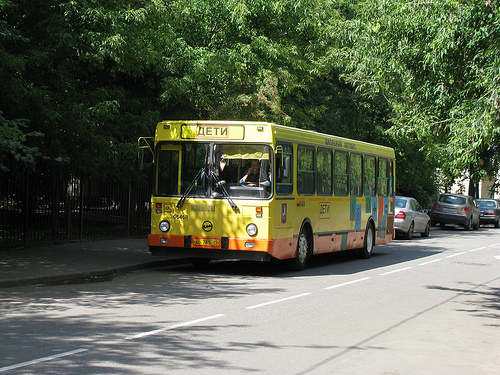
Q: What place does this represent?
A: It represents the street.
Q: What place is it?
A: It is a street.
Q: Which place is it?
A: It is a street.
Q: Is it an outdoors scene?
A: Yes, it is outdoors.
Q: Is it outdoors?
A: Yes, it is outdoors.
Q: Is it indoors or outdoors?
A: It is outdoors.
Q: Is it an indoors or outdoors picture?
A: It is outdoors.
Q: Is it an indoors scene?
A: No, it is outdoors.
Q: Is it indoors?
A: No, it is outdoors.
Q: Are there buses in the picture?
A: Yes, there is a bus.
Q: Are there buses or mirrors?
A: Yes, there is a bus.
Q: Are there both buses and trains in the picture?
A: No, there is a bus but no trains.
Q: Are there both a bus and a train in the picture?
A: No, there is a bus but no trains.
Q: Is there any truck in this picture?
A: No, there are no trucks.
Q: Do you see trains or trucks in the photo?
A: No, there are no trucks or trains.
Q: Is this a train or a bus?
A: This is a bus.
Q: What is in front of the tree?
A: The bus is in front of the tree.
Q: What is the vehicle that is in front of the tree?
A: The vehicle is a bus.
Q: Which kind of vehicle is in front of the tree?
A: The vehicle is a bus.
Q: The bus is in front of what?
A: The bus is in front of the tree.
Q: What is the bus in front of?
A: The bus is in front of the tree.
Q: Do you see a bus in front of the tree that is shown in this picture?
A: Yes, there is a bus in front of the tree.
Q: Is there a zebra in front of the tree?
A: No, there is a bus in front of the tree.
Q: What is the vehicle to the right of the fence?
A: The vehicle is a bus.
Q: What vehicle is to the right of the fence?
A: The vehicle is a bus.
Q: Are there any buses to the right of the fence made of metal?
A: Yes, there is a bus to the right of the fence.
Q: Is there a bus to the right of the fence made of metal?
A: Yes, there is a bus to the right of the fence.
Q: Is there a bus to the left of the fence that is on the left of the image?
A: No, the bus is to the right of the fence.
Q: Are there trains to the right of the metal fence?
A: No, there is a bus to the right of the fence.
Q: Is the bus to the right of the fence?
A: Yes, the bus is to the right of the fence.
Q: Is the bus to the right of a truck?
A: No, the bus is to the right of the fence.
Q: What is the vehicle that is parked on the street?
A: The vehicle is a bus.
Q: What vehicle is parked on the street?
A: The vehicle is a bus.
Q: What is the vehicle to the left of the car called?
A: The vehicle is a bus.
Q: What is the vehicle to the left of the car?
A: The vehicle is a bus.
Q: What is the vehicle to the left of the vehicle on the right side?
A: The vehicle is a bus.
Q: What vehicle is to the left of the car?
A: The vehicle is a bus.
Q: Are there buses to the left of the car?
A: Yes, there is a bus to the left of the car.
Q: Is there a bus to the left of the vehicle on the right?
A: Yes, there is a bus to the left of the car.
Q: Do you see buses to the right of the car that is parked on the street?
A: No, the bus is to the left of the car.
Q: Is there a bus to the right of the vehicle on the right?
A: No, the bus is to the left of the car.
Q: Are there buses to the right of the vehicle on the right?
A: No, the bus is to the left of the car.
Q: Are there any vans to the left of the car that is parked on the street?
A: No, there is a bus to the left of the car.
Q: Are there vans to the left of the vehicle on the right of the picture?
A: No, there is a bus to the left of the car.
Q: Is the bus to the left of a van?
A: No, the bus is to the left of the car.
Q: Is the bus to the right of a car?
A: No, the bus is to the left of a car.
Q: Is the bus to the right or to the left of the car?
A: The bus is to the left of the car.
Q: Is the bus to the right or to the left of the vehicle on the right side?
A: The bus is to the left of the car.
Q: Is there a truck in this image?
A: No, there are no trucks.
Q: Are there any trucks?
A: No, there are no trucks.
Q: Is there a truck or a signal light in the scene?
A: No, there are no trucks or traffic lights.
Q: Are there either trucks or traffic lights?
A: No, there are no trucks or traffic lights.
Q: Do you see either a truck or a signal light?
A: No, there are no trucks or traffic lights.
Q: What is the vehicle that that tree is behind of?
A: The vehicle is a bus.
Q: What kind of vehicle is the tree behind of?
A: The tree is behind the bus.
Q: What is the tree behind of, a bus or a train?
A: The tree is behind a bus.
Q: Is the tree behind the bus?
A: Yes, the tree is behind the bus.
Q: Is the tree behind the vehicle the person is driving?
A: Yes, the tree is behind the bus.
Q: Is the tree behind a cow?
A: No, the tree is behind the bus.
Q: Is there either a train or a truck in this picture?
A: No, there are no trucks or trains.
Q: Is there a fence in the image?
A: Yes, there is a fence.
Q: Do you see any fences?
A: Yes, there is a fence.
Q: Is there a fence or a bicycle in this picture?
A: Yes, there is a fence.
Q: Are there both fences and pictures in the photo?
A: No, there is a fence but no pictures.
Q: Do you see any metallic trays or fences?
A: Yes, there is a metal fence.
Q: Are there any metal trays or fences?
A: Yes, there is a metal fence.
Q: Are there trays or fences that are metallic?
A: Yes, the fence is metallic.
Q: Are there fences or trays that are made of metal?
A: Yes, the fence is made of metal.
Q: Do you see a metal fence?
A: Yes, there is a metal fence.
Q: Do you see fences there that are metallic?
A: Yes, there is a fence that is metallic.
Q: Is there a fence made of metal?
A: Yes, there is a fence that is made of metal.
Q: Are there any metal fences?
A: Yes, there is a fence that is made of metal.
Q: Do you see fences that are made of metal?
A: Yes, there is a fence that is made of metal.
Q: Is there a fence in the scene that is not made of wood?
A: Yes, there is a fence that is made of metal.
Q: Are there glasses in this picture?
A: No, there are no glasses.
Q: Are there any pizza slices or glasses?
A: No, there are no glasses or pizza slices.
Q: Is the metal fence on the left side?
A: Yes, the fence is on the left of the image.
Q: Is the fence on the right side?
A: No, the fence is on the left of the image.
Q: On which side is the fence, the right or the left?
A: The fence is on the left of the image.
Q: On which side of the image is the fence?
A: The fence is on the left of the image.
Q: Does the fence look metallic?
A: Yes, the fence is metallic.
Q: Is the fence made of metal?
A: Yes, the fence is made of metal.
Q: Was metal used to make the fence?
A: Yes, the fence is made of metal.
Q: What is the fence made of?
A: The fence is made of metal.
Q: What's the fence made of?
A: The fence is made of metal.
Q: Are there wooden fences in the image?
A: No, there is a fence but it is metallic.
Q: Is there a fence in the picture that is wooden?
A: No, there is a fence but it is metallic.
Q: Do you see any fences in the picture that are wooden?
A: No, there is a fence but it is metallic.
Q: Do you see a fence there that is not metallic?
A: No, there is a fence but it is metallic.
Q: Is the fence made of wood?
A: No, the fence is made of metal.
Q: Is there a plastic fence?
A: No, there is a fence but it is made of metal.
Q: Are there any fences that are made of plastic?
A: No, there is a fence but it is made of metal.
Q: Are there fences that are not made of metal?
A: No, there is a fence but it is made of metal.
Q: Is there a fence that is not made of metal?
A: No, there is a fence but it is made of metal.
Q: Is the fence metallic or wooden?
A: The fence is metallic.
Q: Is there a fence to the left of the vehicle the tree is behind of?
A: Yes, there is a fence to the left of the bus.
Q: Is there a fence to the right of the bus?
A: No, the fence is to the left of the bus.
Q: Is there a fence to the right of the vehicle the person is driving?
A: No, the fence is to the left of the bus.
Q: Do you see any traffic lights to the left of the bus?
A: No, there is a fence to the left of the bus.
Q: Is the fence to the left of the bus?
A: Yes, the fence is to the left of the bus.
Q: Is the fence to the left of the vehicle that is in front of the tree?
A: Yes, the fence is to the left of the bus.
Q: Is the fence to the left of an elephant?
A: No, the fence is to the left of the bus.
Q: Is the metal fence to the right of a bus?
A: No, the fence is to the left of a bus.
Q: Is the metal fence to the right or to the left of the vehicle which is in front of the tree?
A: The fence is to the left of the bus.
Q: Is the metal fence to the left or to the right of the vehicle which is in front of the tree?
A: The fence is to the left of the bus.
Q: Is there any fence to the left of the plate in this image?
A: Yes, there is a fence to the left of the plate.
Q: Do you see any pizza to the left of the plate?
A: No, there is a fence to the left of the plate.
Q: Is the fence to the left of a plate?
A: Yes, the fence is to the left of a plate.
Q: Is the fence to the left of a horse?
A: No, the fence is to the left of a plate.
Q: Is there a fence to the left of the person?
A: Yes, there is a fence to the left of the person.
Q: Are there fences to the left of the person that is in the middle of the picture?
A: Yes, there is a fence to the left of the person.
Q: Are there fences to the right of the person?
A: No, the fence is to the left of the person.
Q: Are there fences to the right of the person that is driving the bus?
A: No, the fence is to the left of the person.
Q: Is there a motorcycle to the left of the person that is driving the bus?
A: No, there is a fence to the left of the person.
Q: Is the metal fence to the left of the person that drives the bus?
A: Yes, the fence is to the left of the person.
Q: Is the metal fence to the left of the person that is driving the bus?
A: Yes, the fence is to the left of the person.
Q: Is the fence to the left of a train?
A: No, the fence is to the left of the person.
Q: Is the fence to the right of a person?
A: No, the fence is to the left of a person.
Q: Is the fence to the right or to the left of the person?
A: The fence is to the left of the person.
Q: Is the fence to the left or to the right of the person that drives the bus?
A: The fence is to the left of the person.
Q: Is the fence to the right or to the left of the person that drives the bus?
A: The fence is to the left of the person.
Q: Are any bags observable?
A: No, there are no bags.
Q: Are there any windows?
A: Yes, there is a window.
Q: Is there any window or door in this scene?
A: Yes, there is a window.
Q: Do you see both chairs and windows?
A: No, there is a window but no chairs.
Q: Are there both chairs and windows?
A: No, there is a window but no chairs.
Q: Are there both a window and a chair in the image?
A: No, there is a window but no chairs.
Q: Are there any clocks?
A: No, there are no clocks.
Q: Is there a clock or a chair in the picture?
A: No, there are no clocks or chairs.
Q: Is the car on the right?
A: Yes, the car is on the right of the image.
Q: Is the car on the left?
A: No, the car is on the right of the image.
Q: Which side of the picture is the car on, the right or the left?
A: The car is on the right of the image.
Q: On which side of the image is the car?
A: The car is on the right of the image.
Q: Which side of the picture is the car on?
A: The car is on the right of the image.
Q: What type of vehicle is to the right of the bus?
A: The vehicle is a car.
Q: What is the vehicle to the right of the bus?
A: The vehicle is a car.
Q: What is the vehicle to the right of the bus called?
A: The vehicle is a car.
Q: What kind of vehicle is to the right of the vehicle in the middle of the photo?
A: The vehicle is a car.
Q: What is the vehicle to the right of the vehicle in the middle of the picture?
A: The vehicle is a car.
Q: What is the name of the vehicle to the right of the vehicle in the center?
A: The vehicle is a car.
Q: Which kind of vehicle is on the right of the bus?
A: The vehicle is a car.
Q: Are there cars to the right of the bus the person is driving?
A: Yes, there is a car to the right of the bus.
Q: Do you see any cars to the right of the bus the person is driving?
A: Yes, there is a car to the right of the bus.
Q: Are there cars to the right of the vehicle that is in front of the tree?
A: Yes, there is a car to the right of the bus.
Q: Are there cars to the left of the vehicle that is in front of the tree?
A: No, the car is to the right of the bus.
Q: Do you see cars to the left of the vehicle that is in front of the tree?
A: No, the car is to the right of the bus.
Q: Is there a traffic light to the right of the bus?
A: No, there is a car to the right of the bus.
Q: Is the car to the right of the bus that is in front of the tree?
A: Yes, the car is to the right of the bus.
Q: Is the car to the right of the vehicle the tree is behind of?
A: Yes, the car is to the right of the bus.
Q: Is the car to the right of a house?
A: No, the car is to the right of the bus.